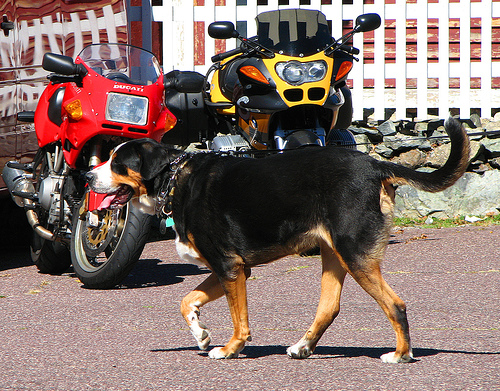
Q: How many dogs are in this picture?
A: One.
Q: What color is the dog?
A: Brown, black and white.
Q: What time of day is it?
A: Daytime.